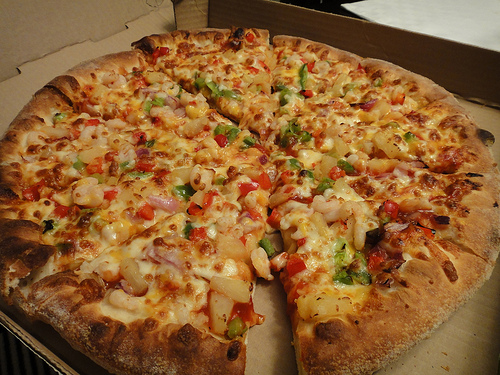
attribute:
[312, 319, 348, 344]
bubble — burnt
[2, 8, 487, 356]
box — is large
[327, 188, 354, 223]
cheese — is melted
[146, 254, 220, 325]
cheese — melted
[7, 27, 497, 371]
pizza — is delicious, is cooked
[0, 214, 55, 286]
crust — Is burnt